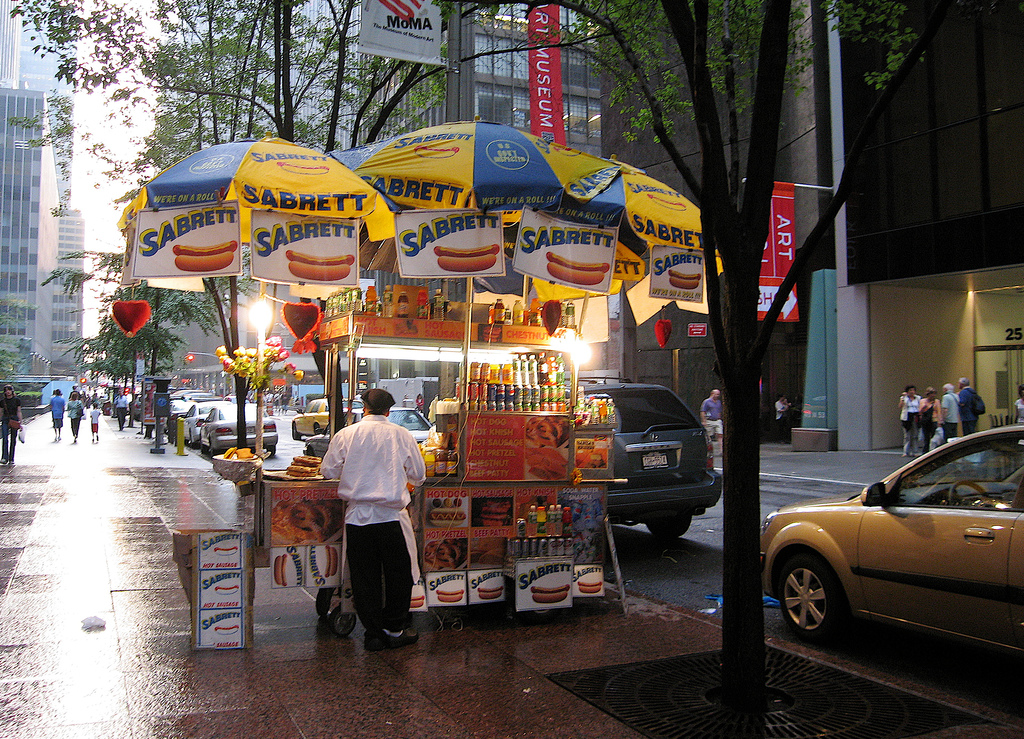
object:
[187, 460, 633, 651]
stand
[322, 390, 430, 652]
working man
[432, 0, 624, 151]
museum banner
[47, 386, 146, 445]
people